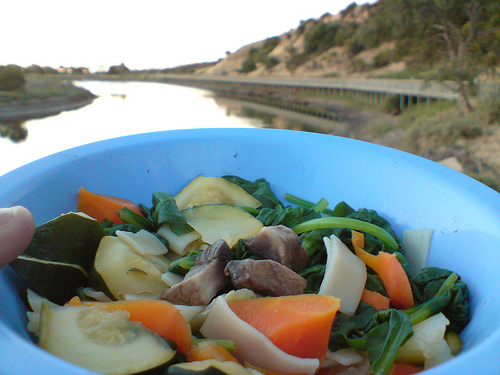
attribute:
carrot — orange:
[218, 288, 344, 369]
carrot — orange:
[72, 183, 142, 221]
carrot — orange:
[127, 290, 197, 340]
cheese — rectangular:
[312, 232, 373, 316]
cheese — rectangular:
[198, 298, 324, 374]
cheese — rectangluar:
[114, 224, 168, 262]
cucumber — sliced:
[182, 200, 265, 250]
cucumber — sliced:
[30, 296, 174, 371]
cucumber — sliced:
[90, 231, 183, 302]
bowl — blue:
[3, 116, 497, 374]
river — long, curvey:
[1, 74, 248, 140]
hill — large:
[179, 3, 499, 73]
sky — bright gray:
[1, 0, 265, 48]